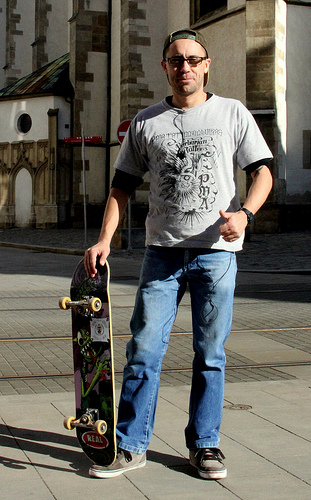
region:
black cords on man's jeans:
[196, 239, 232, 345]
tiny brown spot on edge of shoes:
[211, 470, 224, 480]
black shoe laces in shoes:
[173, 440, 240, 463]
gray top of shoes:
[196, 454, 238, 470]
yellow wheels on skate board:
[54, 288, 108, 318]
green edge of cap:
[158, 27, 222, 49]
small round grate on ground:
[224, 390, 275, 425]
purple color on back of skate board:
[62, 368, 89, 402]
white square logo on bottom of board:
[76, 313, 119, 340]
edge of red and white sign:
[109, 119, 146, 145]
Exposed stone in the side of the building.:
[117, 1, 149, 119]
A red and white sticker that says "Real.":
[76, 426, 107, 450]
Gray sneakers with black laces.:
[89, 440, 228, 485]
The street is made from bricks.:
[232, 273, 296, 390]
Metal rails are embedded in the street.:
[5, 324, 62, 387]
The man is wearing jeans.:
[109, 243, 249, 451]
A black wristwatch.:
[238, 202, 260, 227]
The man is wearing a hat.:
[149, 27, 210, 100]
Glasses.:
[153, 46, 210, 69]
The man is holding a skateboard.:
[46, 19, 290, 476]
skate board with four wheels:
[59, 244, 125, 466]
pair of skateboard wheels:
[60, 402, 112, 439]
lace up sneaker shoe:
[184, 433, 237, 483]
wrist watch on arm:
[216, 176, 272, 245]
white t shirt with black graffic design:
[118, 93, 238, 257]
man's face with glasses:
[160, 52, 219, 96]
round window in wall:
[9, 107, 46, 139]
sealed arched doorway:
[8, 142, 40, 232]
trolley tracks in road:
[236, 319, 308, 374]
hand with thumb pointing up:
[212, 206, 245, 244]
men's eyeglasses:
[161, 54, 208, 65]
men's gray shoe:
[187, 445, 227, 480]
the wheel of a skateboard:
[92, 419, 107, 435]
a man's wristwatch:
[237, 204, 255, 221]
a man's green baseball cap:
[156, 26, 210, 87]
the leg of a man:
[185, 250, 232, 450]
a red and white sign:
[114, 120, 135, 142]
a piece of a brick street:
[28, 381, 46, 388]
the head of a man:
[161, 27, 211, 94]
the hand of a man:
[215, 209, 244, 242]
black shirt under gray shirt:
[108, 92, 176, 210]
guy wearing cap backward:
[142, 27, 243, 154]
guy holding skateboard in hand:
[62, 14, 269, 492]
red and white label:
[77, 430, 117, 459]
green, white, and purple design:
[70, 324, 120, 425]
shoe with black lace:
[181, 436, 251, 488]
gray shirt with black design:
[137, 103, 265, 218]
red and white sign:
[106, 114, 151, 157]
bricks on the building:
[110, 17, 170, 120]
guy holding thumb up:
[147, 18, 268, 237]